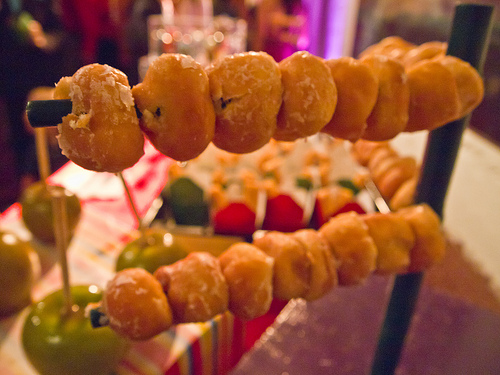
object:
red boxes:
[210, 202, 257, 242]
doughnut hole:
[218, 242, 276, 321]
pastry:
[153, 251, 230, 322]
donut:
[53, 63, 145, 175]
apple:
[20, 285, 131, 375]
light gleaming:
[31, 315, 61, 346]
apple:
[1, 230, 43, 316]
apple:
[21, 181, 83, 243]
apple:
[115, 233, 187, 274]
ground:
[415, 161, 470, 206]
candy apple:
[50, 190, 71, 316]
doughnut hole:
[98, 267, 172, 341]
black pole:
[25, 99, 72, 129]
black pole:
[370, 1, 498, 374]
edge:
[229, 296, 295, 375]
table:
[0, 82, 389, 373]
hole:
[220, 98, 232, 109]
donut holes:
[131, 36, 486, 162]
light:
[89, 285, 99, 294]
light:
[51, 160, 124, 200]